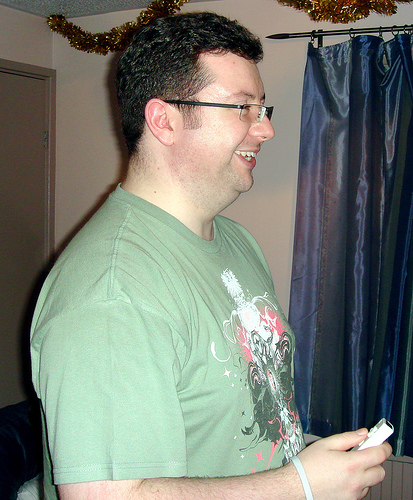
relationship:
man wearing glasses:
[41, 27, 360, 493] [173, 89, 278, 122]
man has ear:
[41, 27, 360, 493] [138, 95, 187, 156]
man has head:
[41, 27, 360, 493] [107, 22, 260, 172]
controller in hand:
[345, 417, 393, 450] [289, 419, 396, 496]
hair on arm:
[106, 10, 264, 163] [52, 460, 302, 499]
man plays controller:
[41, 27, 360, 493] [345, 417, 393, 450]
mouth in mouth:
[233, 146, 262, 170] [233, 146, 262, 170]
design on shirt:
[193, 281, 313, 416] [35, 185, 342, 485]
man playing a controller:
[41, 27, 360, 493] [345, 417, 393, 450]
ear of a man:
[143, 98, 184, 146] [41, 27, 360, 493]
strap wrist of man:
[288, 452, 309, 497] [83, 20, 292, 287]